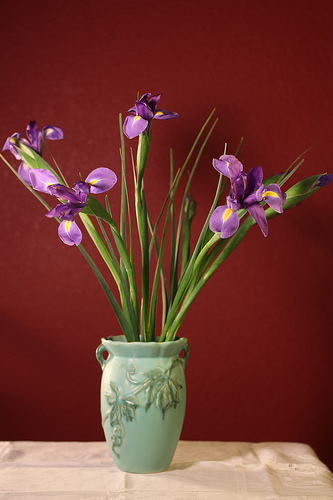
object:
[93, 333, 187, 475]
vase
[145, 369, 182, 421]
design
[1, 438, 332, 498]
table cloth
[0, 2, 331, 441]
wall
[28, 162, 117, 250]
flower bloom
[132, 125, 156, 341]
flower stem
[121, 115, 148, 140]
flower petal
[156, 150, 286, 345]
bouquet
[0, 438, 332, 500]
table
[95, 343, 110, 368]
handle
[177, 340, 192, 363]
handle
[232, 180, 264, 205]
flower bud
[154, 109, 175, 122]
flower petal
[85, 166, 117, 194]
flower petal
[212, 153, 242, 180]
flower petal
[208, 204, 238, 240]
flower petal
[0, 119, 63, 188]
flower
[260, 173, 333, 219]
flower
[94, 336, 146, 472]
light reflection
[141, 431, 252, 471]
shadow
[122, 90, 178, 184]
flower bloom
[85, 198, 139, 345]
flower stem